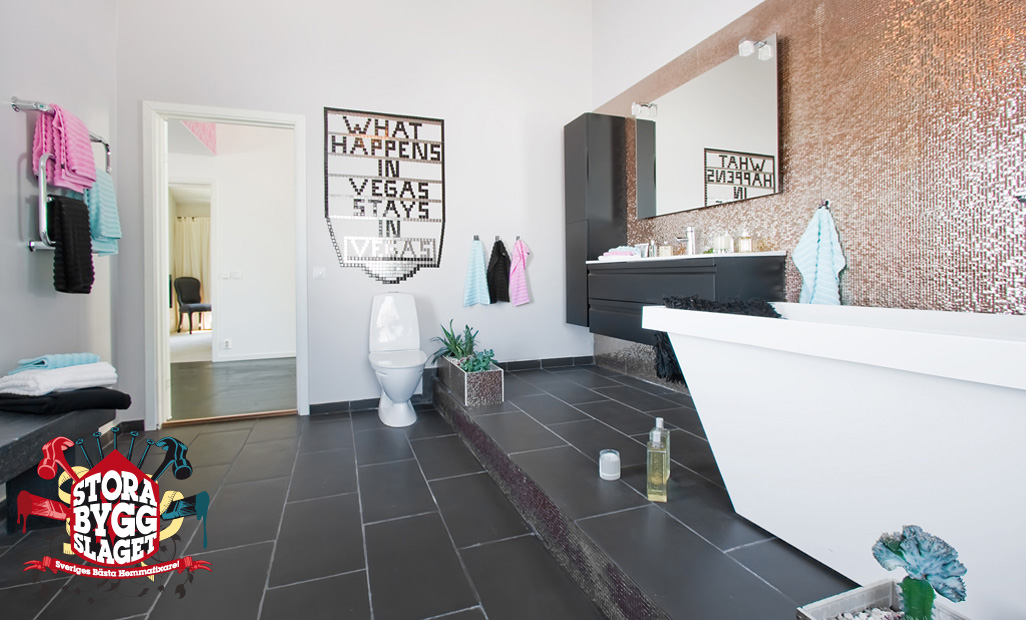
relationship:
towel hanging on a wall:
[38, 119, 116, 208] [277, 41, 480, 89]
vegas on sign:
[344, 175, 431, 201] [323, 102, 447, 284]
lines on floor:
[4, 354, 856, 617] [4, 354, 856, 617]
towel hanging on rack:
[27, 192, 118, 303] [6, 95, 116, 251]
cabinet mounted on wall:
[562, 110, 623, 324] [592, 3, 1024, 402]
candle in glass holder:
[597, 445, 621, 478] [601, 449, 623, 480]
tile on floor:
[722, 528, 854, 602] [4, 354, 856, 617]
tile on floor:
[653, 483, 772, 559] [4, 354, 856, 617]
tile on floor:
[579, 500, 806, 619] [4, 354, 856, 617]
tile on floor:
[502, 442, 662, 529] [4, 354, 856, 617]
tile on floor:
[465, 397, 576, 479] [4, 354, 856, 617]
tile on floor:
[458, 530, 616, 619] [4, 354, 856, 617]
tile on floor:
[411, 427, 493, 484] [4, 354, 856, 617]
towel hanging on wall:
[504, 231, 535, 316] [127, 0, 591, 414]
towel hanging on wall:
[484, 237, 513, 304] [127, 0, 591, 414]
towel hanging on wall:
[465, 239, 498, 308] [127, 0, 591, 414]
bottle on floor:
[652, 411, 672, 483] [4, 354, 856, 617]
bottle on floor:
[642, 425, 675, 501] [4, 354, 856, 617]